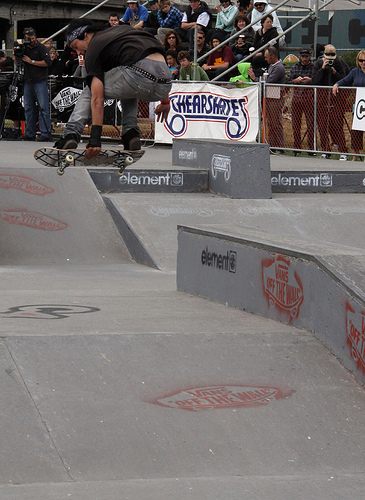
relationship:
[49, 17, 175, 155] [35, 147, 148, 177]
person on top of skateboard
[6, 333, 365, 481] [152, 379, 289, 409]
ramp has vans logo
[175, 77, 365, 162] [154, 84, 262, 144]
fence has sign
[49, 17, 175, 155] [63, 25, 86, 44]
person has headband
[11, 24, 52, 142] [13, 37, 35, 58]
man holding video camera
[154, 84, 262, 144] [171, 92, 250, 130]
sign has writing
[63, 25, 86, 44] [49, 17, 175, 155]
headband on person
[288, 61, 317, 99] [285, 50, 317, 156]
shirt on man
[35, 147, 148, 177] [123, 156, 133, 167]
skateboard has wheel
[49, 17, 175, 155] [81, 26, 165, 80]
person wearing shirt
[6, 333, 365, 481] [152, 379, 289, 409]
ramp has a vans logo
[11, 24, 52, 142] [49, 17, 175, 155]
man filming person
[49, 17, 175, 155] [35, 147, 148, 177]
person holding skateboard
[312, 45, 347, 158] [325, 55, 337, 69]
woman holding camera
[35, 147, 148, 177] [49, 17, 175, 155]
skateboard underneath person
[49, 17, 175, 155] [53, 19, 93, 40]
person has hair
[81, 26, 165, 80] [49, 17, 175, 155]
shirt worn by person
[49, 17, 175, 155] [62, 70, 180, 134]
person wearing jeans